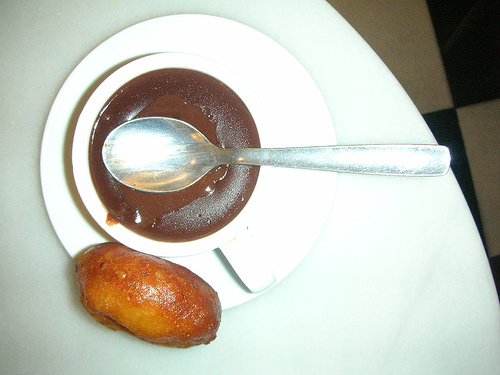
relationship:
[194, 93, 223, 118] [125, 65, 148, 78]
sauce in bowl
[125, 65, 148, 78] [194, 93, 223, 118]
bowl of sauce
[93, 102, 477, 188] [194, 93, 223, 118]
spoon in sauce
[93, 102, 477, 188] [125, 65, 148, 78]
spoon in bowl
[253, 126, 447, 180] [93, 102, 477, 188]
handle of spoon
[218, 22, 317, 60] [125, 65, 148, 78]
plate under bowl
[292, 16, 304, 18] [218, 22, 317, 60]
table under plate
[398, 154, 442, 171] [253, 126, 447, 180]
reflection on handle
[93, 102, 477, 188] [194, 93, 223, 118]
spoon on sauce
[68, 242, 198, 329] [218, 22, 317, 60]
pastry by plate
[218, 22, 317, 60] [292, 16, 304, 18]
plate on table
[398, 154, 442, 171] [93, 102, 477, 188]
reflection on spoon